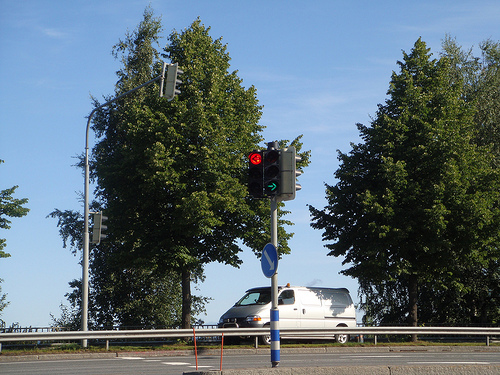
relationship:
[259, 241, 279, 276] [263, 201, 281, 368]
sign on pole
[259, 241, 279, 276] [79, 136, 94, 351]
sign on pole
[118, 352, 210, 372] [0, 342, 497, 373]
white lines on road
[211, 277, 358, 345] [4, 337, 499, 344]
van in grass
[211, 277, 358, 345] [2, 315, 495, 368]
van on road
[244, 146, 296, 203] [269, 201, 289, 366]
traffic light on pole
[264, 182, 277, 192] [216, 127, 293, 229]
arrow on traffic light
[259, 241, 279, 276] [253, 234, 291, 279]
sign has arrow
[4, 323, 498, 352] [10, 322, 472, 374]
rail on road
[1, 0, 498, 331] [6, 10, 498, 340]
blue sky in distance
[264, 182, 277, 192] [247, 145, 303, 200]
arrow on traffic light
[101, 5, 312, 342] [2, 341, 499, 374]
tree on road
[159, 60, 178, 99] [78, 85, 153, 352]
traffic light on pole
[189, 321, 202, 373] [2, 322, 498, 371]
stick near road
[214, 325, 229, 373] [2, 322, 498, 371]
stick near road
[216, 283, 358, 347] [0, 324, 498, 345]
van behind tail